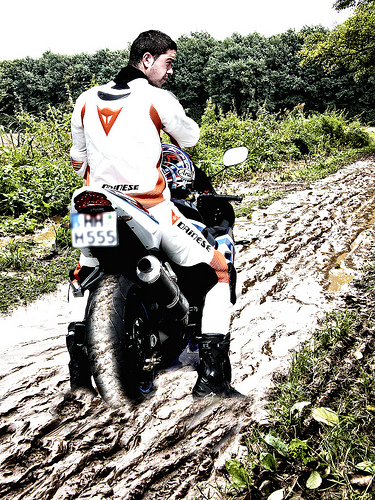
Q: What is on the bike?
A: A man.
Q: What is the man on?
A: A bike.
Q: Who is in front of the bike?
A: No one.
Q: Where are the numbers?
A: On license plate.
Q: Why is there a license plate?
A: Register vehicle.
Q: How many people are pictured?
A: One.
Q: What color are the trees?
A: Green.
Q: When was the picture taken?
A: Daytime.